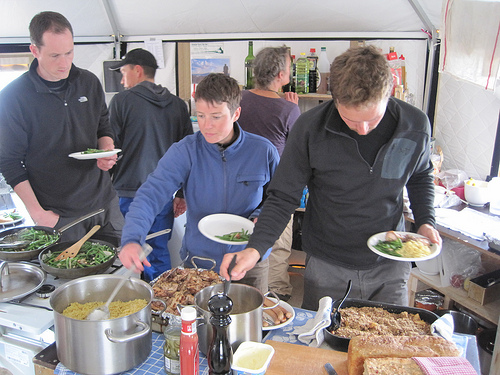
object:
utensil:
[50, 223, 101, 266]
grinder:
[194, 290, 233, 374]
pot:
[47, 273, 154, 375]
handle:
[104, 322, 151, 346]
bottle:
[176, 305, 202, 374]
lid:
[178, 305, 199, 322]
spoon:
[83, 242, 157, 323]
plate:
[195, 211, 258, 246]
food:
[216, 228, 254, 243]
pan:
[0, 209, 108, 262]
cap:
[100, 48, 163, 72]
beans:
[0, 229, 58, 250]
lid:
[0, 258, 47, 306]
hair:
[22, 8, 71, 53]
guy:
[0, 8, 129, 242]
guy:
[218, 43, 442, 307]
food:
[398, 242, 428, 259]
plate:
[367, 231, 441, 264]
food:
[386, 232, 422, 244]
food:
[371, 237, 411, 257]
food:
[81, 149, 108, 154]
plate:
[66, 148, 120, 163]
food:
[206, 289, 249, 309]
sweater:
[115, 123, 282, 272]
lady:
[115, 72, 279, 298]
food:
[61, 298, 144, 320]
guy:
[108, 43, 194, 282]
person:
[114, 71, 281, 296]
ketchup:
[168, 301, 204, 375]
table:
[0, 178, 500, 374]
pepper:
[208, 290, 232, 374]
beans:
[217, 229, 252, 245]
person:
[1, 12, 124, 249]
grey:
[0, 60, 120, 220]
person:
[105, 49, 192, 283]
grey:
[102, 80, 193, 199]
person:
[237, 43, 301, 251]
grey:
[239, 86, 302, 158]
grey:
[243, 100, 441, 273]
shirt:
[243, 99, 437, 271]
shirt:
[0, 59, 120, 218]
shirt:
[107, 78, 193, 199]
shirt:
[236, 89, 302, 160]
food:
[293, 55, 319, 95]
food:
[316, 45, 330, 93]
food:
[307, 48, 319, 96]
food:
[385, 52, 407, 97]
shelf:
[241, 40, 423, 101]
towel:
[288, 294, 334, 349]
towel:
[428, 309, 457, 342]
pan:
[317, 296, 446, 354]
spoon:
[49, 223, 104, 266]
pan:
[33, 227, 172, 280]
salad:
[46, 243, 111, 268]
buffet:
[0, 184, 500, 373]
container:
[223, 339, 280, 374]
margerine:
[239, 349, 266, 370]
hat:
[102, 46, 160, 74]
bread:
[348, 334, 477, 373]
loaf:
[362, 354, 475, 374]